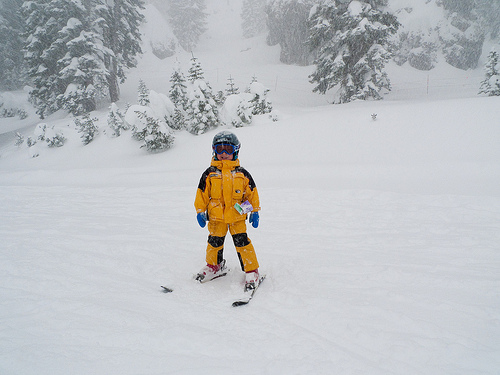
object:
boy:
[186, 129, 279, 308]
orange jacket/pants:
[196, 163, 263, 281]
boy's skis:
[158, 268, 263, 307]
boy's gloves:
[194, 210, 211, 228]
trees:
[472, 32, 499, 100]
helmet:
[208, 129, 242, 156]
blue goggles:
[213, 143, 236, 156]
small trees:
[6, 2, 417, 114]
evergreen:
[0, 0, 500, 119]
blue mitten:
[247, 208, 260, 227]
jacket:
[196, 160, 260, 220]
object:
[369, 112, 379, 120]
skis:
[158, 270, 279, 312]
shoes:
[193, 262, 270, 291]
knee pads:
[230, 233, 251, 248]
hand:
[188, 208, 215, 229]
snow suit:
[190, 150, 271, 273]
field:
[0, 95, 494, 365]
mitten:
[248, 209, 260, 227]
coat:
[190, 159, 263, 239]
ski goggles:
[210, 141, 238, 156]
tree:
[300, 3, 399, 104]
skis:
[157, 264, 229, 295]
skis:
[230, 269, 269, 312]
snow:
[1, 99, 500, 373]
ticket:
[230, 198, 254, 218]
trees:
[17, 2, 148, 118]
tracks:
[4, 165, 498, 372]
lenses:
[214, 139, 233, 154]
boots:
[195, 259, 226, 282]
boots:
[242, 271, 265, 291]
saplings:
[165, 51, 225, 137]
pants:
[195, 225, 265, 279]